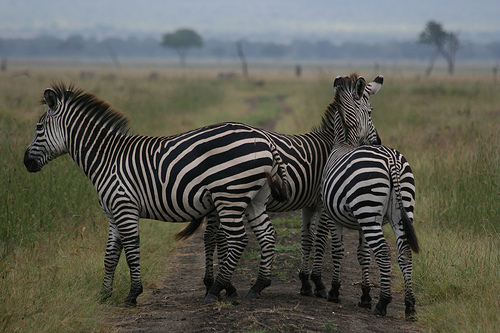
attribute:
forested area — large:
[2, 19, 496, 76]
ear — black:
[41, 89, 75, 115]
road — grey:
[162, 236, 296, 330]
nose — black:
[22, 148, 43, 174]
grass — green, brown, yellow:
[1, 58, 498, 331]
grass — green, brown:
[31, 236, 466, 330]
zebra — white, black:
[318, 78, 432, 312]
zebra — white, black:
[235, 82, 365, 209]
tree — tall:
[395, 17, 470, 89]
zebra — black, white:
[24, 74, 280, 311]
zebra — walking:
[13, 72, 278, 299]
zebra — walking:
[173, 70, 388, 295]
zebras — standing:
[33, 73, 410, 311]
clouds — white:
[45, 20, 70, 30]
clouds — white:
[285, 17, 418, 34]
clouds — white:
[443, 22, 498, 34]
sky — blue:
[3, 0, 498, 40]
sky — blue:
[3, 0, 499, 52]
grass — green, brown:
[25, 180, 79, 228]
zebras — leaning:
[306, 62, 456, 315]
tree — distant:
[152, 26, 207, 63]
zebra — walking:
[320, 72, 420, 319]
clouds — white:
[0, 16, 482, 43]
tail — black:
[395, 206, 425, 255]